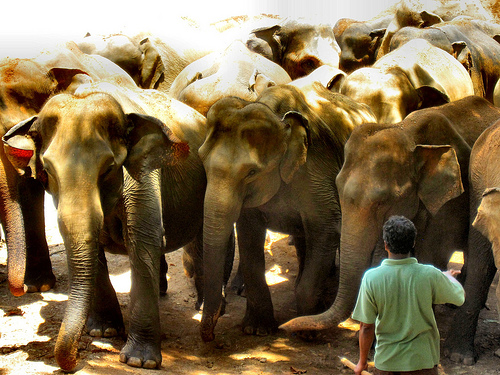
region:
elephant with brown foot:
[114, 317, 167, 371]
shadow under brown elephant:
[173, 315, 209, 372]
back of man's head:
[384, 219, 413, 254]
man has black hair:
[378, 222, 415, 261]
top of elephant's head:
[216, 84, 273, 211]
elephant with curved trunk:
[336, 248, 363, 353]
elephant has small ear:
[413, 135, 464, 217]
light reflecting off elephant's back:
[158, 29, 242, 99]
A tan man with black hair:
[353, 215, 447, 373]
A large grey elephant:
[10, 80, 209, 367]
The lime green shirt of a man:
[351, 258, 464, 370]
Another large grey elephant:
[194, 85, 377, 340]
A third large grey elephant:
[278, 94, 498, 341]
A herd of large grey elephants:
[0, 1, 498, 370]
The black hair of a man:
[381, 213, 418, 256]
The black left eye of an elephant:
[243, 164, 260, 181]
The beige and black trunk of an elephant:
[55, 188, 105, 369]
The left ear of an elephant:
[115, 111, 190, 186]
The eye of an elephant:
[247, 169, 256, 175]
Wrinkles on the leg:
[126, 193, 146, 201]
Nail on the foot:
[130, 360, 138, 365]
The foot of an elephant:
[122, 347, 161, 364]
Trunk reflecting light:
[65, 204, 92, 233]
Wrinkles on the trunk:
[73, 264, 89, 278]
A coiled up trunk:
[56, 345, 71, 360]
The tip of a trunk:
[278, 326, 290, 332]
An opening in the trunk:
[281, 328, 286, 332]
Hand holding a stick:
[356, 366, 362, 372]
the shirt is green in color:
[368, 265, 430, 357]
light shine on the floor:
[236, 340, 282, 370]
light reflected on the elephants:
[202, 18, 387, 112]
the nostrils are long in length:
[57, 185, 82, 373]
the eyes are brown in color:
[238, 155, 267, 185]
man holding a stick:
[338, 346, 364, 373]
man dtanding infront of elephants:
[362, 223, 485, 371]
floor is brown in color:
[254, 335, 291, 372]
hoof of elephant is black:
[126, 328, 164, 370]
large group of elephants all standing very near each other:
[2, 7, 491, 370]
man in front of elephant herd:
[346, 212, 468, 373]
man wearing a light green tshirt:
[344, 250, 466, 373]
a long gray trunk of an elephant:
[39, 182, 114, 372]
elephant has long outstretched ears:
[0, 92, 183, 190]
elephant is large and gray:
[189, 77, 384, 363]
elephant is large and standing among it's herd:
[278, 92, 496, 353]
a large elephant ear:
[119, 109, 195, 186]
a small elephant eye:
[241, 163, 266, 180]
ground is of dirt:
[2, 202, 498, 372]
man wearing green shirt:
[345, 207, 462, 373]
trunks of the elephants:
[8, 167, 400, 369]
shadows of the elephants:
[5, 210, 482, 369]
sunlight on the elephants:
[8, 35, 473, 115]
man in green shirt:
[326, 209, 471, 365]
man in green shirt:
[346, 208, 474, 367]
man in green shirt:
[333, 206, 478, 363]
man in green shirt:
[341, 213, 475, 364]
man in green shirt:
[326, 208, 480, 368]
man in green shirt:
[340, 208, 475, 371]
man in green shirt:
[333, 209, 473, 371]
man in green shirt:
[329, 200, 471, 367]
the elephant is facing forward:
[9, 78, 216, 370]